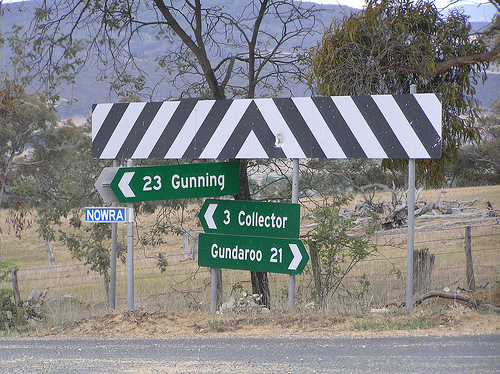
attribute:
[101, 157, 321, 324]
signs — green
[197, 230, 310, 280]
sign — pointing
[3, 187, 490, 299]
hill — behind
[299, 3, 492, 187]
trees — behind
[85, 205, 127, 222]
blue sign — small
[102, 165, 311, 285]
signs — white 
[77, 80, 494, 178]
sign — white 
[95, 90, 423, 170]
sign — white, striped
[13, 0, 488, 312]
tree — green 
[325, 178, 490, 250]
pile — dead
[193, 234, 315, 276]
sign — pointing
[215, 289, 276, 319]
rocks — grey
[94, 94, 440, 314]
barrier — white 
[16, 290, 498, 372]
road — gravel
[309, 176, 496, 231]
branch — behind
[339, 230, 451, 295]
fence — wood, wire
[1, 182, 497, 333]
field — behind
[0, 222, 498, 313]
fence — behind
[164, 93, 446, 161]
sign — white 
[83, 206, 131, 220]
sign — white 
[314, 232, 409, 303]
fence — behind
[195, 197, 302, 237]
sign — white , pointing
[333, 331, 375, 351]
road — gravel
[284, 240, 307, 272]
arrow — pointing, white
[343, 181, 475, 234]
tree branches — dead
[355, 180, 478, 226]
sticks — piled